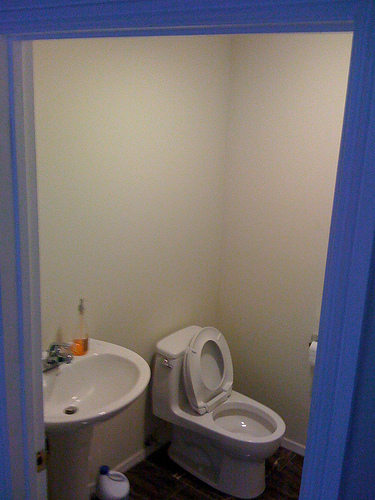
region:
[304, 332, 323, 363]
edge of the toilet paper roll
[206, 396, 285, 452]
clean toilet bowl in the bathroom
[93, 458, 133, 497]
top of a white container of liquid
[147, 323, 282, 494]
white toilet in the bathroom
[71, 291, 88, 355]
a container of soap next to the sink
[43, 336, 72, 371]
silver sink handle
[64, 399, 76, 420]
silver drain in the white sink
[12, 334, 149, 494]
a white sink in the bathroom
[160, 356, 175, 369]
flushing handle on the toilet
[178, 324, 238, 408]
lifted toilet lid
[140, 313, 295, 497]
A TOILET IN A BATHROOM.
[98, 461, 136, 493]
A BOTTLE OF BLEACH.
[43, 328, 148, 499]
A TALL WHITE SINK.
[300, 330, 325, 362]
TOILET PAPER ON A ROLL.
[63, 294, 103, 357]
A PARTIALLY FULL SOAP DISPENSER.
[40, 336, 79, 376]
THE CHROME SINK FAUCET.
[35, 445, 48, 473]
THE GOLDEN DOOR JAMB.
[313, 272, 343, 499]
THE WALL AND DOOR FRAME ARE BLUE.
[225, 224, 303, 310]
THE WALLS ARE STERILE WHITE.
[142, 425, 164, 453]
THE SHUT OFF VALVE FOR THE TOILET.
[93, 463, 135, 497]
white and blue top of a liquid bottle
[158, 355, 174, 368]
silver flushing apparatus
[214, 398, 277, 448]
clean white toilet bowl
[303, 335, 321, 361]
edge of a the toilet paper roll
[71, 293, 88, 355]
a container of soap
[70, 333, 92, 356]
orange soap in the bottom of the container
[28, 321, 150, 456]
a sink in the bathroom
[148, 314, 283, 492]
a porcelain white toilet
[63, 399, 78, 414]
silver drain in the sink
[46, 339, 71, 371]
silver faucet in the sink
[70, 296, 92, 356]
Orange soap in a soap pump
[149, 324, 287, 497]
White porcelain toilet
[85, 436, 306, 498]
Dark tiled bathroom floor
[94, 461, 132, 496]
White plastic bottle of bleach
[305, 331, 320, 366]
Roll of toilet paper on a holder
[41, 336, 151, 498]
White porcelain bathroom sink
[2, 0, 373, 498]
Blue painted door trim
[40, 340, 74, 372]
Silver handle and faucet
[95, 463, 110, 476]
Blue cap on a bottle of bleach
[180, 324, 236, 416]
Open white toilet seat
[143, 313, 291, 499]
a toilet in the bathroom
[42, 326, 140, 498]
a small sink in the bathroom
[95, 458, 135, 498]
a bottle of bleach on the bathroom floor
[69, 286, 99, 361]
handsoap on the bathroom sink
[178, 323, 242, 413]
toilet seat that is up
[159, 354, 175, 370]
flush handle to the toilet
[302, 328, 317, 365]
toilet paper hanging from the wall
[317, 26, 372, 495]
a blue shower curtain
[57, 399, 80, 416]
drain to the sink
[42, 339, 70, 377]
nozzle to the sink